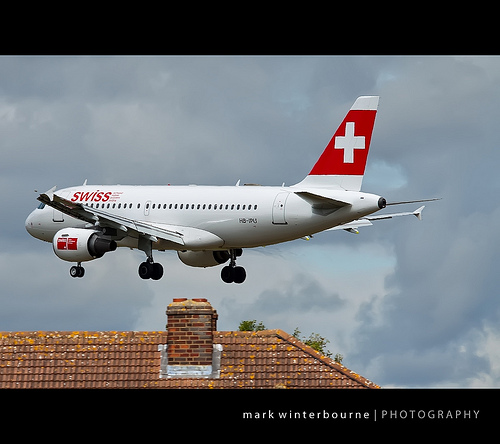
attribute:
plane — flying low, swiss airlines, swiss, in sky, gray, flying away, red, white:
[25, 95, 442, 282]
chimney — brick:
[166, 297, 219, 379]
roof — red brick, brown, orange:
[1, 330, 382, 389]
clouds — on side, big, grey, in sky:
[0, 57, 499, 388]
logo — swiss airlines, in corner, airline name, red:
[72, 191, 113, 202]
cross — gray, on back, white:
[334, 122, 365, 164]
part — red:
[307, 111, 377, 175]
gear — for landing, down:
[220, 248, 247, 282]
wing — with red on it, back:
[294, 190, 351, 206]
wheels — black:
[139, 262, 165, 281]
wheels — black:
[221, 265, 247, 283]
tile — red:
[12, 358, 40, 368]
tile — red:
[54, 366, 78, 374]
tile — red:
[141, 366, 162, 374]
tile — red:
[244, 357, 258, 367]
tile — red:
[308, 371, 325, 378]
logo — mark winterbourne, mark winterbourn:
[241, 408, 376, 419]